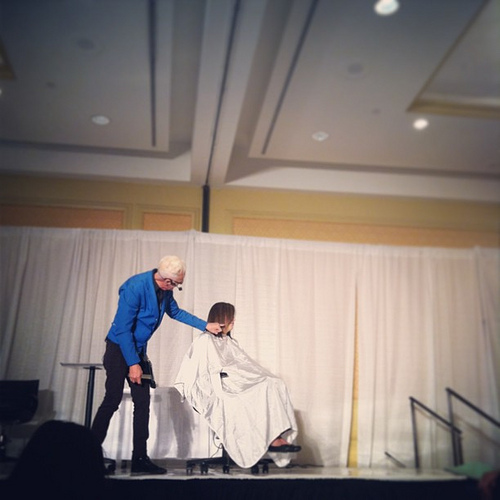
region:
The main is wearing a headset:
[135, 231, 197, 303]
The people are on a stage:
[31, 233, 463, 490]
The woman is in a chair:
[152, 275, 310, 474]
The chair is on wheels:
[172, 437, 288, 483]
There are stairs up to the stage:
[389, 360, 499, 469]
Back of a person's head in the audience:
[10, 411, 112, 498]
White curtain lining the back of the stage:
[21, 226, 472, 447]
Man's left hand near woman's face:
[192, 307, 249, 346]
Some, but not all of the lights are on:
[296, 40, 451, 172]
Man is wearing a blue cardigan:
[93, 253, 220, 391]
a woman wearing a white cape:
[172, 301, 303, 468]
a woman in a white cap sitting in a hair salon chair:
[176, 301, 303, 473]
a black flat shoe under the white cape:
[270, 442, 302, 453]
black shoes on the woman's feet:
[265, 443, 299, 453]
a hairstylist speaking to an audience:
[92, 254, 224, 473]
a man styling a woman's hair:
[91, 253, 226, 476]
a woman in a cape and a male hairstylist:
[86, 255, 302, 476]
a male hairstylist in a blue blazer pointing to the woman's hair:
[92, 252, 227, 474]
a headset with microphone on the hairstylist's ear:
[163, 275, 187, 292]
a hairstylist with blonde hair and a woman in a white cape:
[88, 253, 303, 478]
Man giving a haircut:
[95, 249, 197, 475]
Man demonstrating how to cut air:
[81, 244, 216, 478]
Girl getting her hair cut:
[190, 293, 320, 459]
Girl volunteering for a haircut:
[184, 298, 308, 463]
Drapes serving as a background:
[192, 231, 353, 468]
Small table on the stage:
[57, 359, 114, 479]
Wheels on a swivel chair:
[177, 457, 277, 475]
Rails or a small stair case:
[401, 376, 498, 463]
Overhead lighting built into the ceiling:
[404, 110, 439, 131]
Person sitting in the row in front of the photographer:
[8, 401, 122, 498]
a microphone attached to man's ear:
[161, 249, 188, 302]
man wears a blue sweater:
[103, 267, 209, 364]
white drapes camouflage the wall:
[6, 221, 496, 496]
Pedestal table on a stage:
[33, 339, 140, 499]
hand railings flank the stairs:
[406, 371, 499, 474]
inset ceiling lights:
[295, 1, 442, 176]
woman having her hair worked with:
[178, 299, 300, 469]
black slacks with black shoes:
[67, 341, 169, 499]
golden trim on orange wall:
[4, 162, 499, 239]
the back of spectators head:
[4, 411, 136, 498]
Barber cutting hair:
[87, 201, 321, 472]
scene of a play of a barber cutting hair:
[15, 194, 442, 451]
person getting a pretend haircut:
[162, 266, 314, 481]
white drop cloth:
[179, 323, 302, 472]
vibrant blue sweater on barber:
[94, 258, 223, 400]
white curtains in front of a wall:
[148, 206, 415, 446]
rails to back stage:
[387, 380, 497, 455]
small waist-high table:
[22, 326, 174, 499]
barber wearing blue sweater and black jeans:
[86, 249, 194, 484]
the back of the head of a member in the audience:
[22, 392, 105, 498]